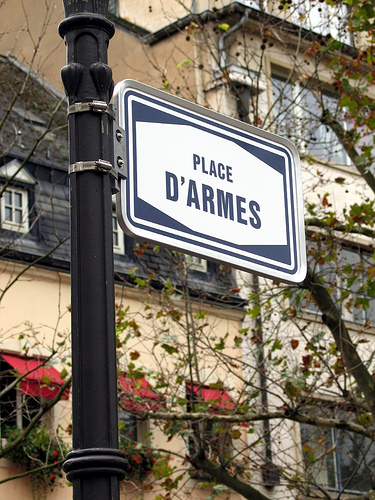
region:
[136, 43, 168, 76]
part fo a wall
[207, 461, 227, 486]
part of a branch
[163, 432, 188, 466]
part of a tree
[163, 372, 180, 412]
part of a tree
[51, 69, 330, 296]
a street sign near the building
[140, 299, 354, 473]
trees and leaves in the picture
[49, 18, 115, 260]
a street sign pole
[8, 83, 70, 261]
a gray roof on a house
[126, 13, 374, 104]
a brown building on the street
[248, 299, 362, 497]
awhite building with a window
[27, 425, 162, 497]
red berries with leaves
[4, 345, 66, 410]
red window covering on the building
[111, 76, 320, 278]
the street sign is blue and white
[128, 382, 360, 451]
a branch on a tree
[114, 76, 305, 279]
white and blue sign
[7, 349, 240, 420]
red canopies over three windows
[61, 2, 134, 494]
black pole sign is attached to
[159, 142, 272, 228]
blue lettering on white sign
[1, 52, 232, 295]
black roof of building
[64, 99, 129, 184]
silver brackets attaching sign to pole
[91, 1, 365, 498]
leaves and branches of tree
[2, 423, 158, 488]
two plants hanging outside windows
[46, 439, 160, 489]
red flowers on plants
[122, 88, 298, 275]
blue edge around white sign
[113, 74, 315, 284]
A sign sayig Place D'armes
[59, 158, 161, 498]
A black sign pole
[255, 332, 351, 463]
A tree with green leaves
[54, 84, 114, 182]
A chrome metal clamp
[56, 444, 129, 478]
Trim on sign pole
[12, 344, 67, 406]
A red window awning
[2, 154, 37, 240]
A window on second floor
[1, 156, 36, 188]
Trim over white window on second floor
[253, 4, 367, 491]
A tall white building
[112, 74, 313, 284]
A blue and white sign with metal trim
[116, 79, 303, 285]
Street sign saying Place D'Armes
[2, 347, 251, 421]
3 Red awnings behind street sign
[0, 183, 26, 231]
Window on second floor of building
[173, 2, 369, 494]
Tree branches next to and behind street sign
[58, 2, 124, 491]
Pole holding street sign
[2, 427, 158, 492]
Flower baskets under windows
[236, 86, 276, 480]
Gutter on front of building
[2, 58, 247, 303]
Black roof of building behind street sign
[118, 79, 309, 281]
Black and white street sign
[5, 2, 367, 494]
Two buildings located next to street sign